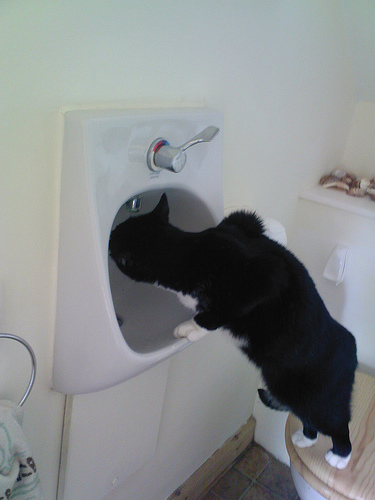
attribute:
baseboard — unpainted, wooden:
[166, 416, 257, 498]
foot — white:
[171, 318, 205, 343]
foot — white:
[290, 426, 318, 449]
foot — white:
[322, 445, 354, 470]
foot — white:
[291, 430, 318, 450]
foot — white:
[324, 448, 350, 467]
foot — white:
[170, 317, 197, 335]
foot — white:
[186, 326, 204, 341]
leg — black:
[174, 286, 270, 340]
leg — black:
[318, 372, 351, 468]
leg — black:
[293, 418, 318, 449]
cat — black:
[63, 174, 289, 300]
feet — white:
[283, 420, 371, 483]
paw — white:
[325, 445, 353, 472]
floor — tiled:
[171, 430, 316, 498]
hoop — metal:
[0, 323, 92, 482]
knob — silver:
[152, 109, 236, 178]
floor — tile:
[245, 455, 279, 490]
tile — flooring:
[211, 466, 254, 497]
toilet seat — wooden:
[280, 364, 373, 498]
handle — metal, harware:
[145, 122, 217, 175]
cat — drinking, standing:
[101, 184, 356, 455]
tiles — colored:
[207, 441, 297, 500]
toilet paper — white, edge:
[259, 216, 288, 247]